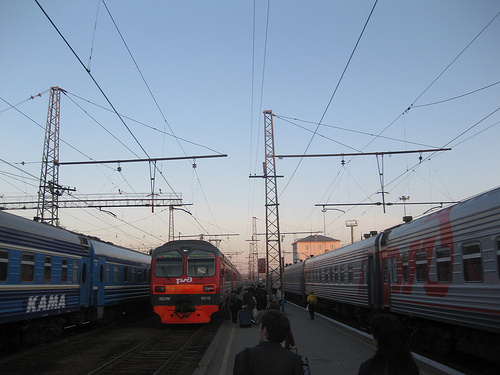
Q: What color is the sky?
A: Blue.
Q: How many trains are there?
A: Three.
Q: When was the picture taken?
A: Daytime.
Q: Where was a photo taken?
A: At a train station.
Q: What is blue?
A: Train on left.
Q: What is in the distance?
A: A brown building.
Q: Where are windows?
A: On trains.